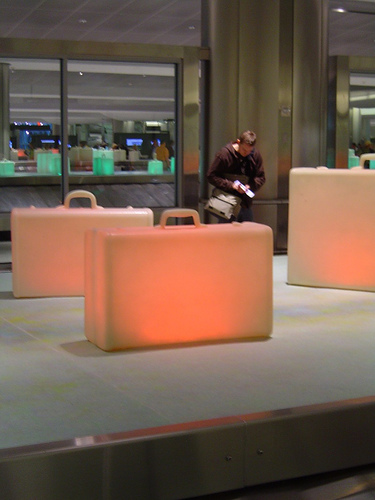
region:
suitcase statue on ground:
[72, 212, 294, 343]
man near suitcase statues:
[202, 119, 272, 219]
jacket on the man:
[212, 144, 259, 187]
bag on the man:
[205, 184, 244, 218]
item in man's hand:
[233, 177, 258, 203]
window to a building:
[6, 62, 179, 197]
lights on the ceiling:
[69, 13, 198, 45]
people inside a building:
[74, 130, 175, 163]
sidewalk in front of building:
[31, 350, 241, 409]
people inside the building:
[88, 133, 172, 163]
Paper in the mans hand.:
[236, 179, 262, 203]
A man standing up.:
[208, 131, 267, 226]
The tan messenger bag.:
[206, 184, 241, 219]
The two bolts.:
[214, 444, 280, 466]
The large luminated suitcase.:
[71, 221, 276, 352]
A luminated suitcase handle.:
[157, 205, 205, 233]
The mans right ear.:
[231, 137, 239, 146]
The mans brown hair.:
[240, 130, 256, 146]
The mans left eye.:
[245, 147, 251, 151]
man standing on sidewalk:
[208, 132, 273, 224]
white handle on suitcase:
[165, 201, 207, 233]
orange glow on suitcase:
[150, 276, 216, 344]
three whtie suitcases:
[4, 162, 373, 343]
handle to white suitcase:
[48, 189, 103, 219]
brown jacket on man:
[206, 149, 270, 192]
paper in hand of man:
[231, 178, 255, 203]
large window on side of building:
[0, 65, 195, 204]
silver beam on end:
[112, 407, 331, 493]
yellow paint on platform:
[50, 379, 73, 398]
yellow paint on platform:
[115, 369, 141, 402]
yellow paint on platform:
[24, 327, 55, 351]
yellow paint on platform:
[30, 364, 47, 388]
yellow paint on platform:
[13, 393, 45, 408]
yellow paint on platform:
[13, 308, 35, 334]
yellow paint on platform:
[278, 302, 296, 328]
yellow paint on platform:
[306, 312, 333, 355]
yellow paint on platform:
[327, 307, 352, 326]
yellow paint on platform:
[338, 296, 365, 326]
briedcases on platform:
[6, 184, 284, 367]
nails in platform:
[215, 443, 275, 468]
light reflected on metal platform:
[65, 429, 115, 459]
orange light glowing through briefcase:
[124, 251, 246, 345]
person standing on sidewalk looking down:
[195, 120, 276, 223]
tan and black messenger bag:
[204, 138, 254, 223]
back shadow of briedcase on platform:
[46, 327, 106, 372]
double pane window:
[6, 53, 183, 237]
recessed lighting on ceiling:
[73, 4, 201, 43]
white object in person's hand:
[227, 176, 258, 201]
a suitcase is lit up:
[89, 216, 372, 417]